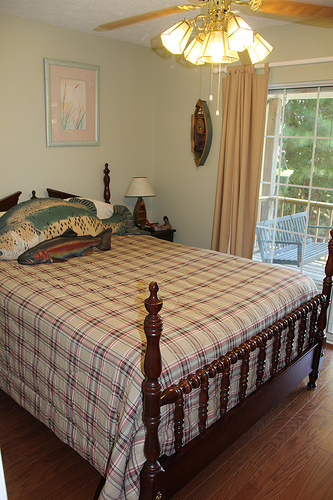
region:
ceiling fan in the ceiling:
[132, 10, 297, 81]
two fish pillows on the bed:
[6, 180, 145, 271]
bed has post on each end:
[137, 295, 187, 389]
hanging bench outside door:
[267, 152, 326, 272]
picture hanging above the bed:
[36, 51, 136, 156]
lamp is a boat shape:
[124, 195, 157, 240]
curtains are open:
[213, 71, 283, 300]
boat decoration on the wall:
[186, 90, 224, 183]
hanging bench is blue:
[269, 216, 331, 266]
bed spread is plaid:
[127, 241, 230, 299]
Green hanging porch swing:
[256, 214, 327, 258]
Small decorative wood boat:
[189, 94, 209, 166]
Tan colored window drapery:
[217, 68, 257, 254]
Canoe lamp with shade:
[124, 174, 152, 227]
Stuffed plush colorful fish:
[16, 228, 110, 265]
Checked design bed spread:
[5, 265, 133, 403]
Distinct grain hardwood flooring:
[254, 419, 330, 485]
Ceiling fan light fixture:
[162, 18, 268, 64]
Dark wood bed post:
[143, 279, 160, 492]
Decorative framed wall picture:
[43, 56, 100, 146]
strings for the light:
[199, 50, 231, 115]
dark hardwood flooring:
[227, 411, 296, 475]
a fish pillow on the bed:
[13, 217, 123, 268]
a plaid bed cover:
[3, 194, 299, 470]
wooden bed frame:
[114, 257, 331, 496]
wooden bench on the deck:
[238, 209, 331, 263]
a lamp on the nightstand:
[117, 166, 162, 235]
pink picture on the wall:
[37, 44, 115, 163]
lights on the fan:
[157, 22, 279, 74]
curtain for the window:
[213, 68, 290, 279]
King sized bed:
[0, 164, 331, 497]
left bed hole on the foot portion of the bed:
[139, 281, 165, 496]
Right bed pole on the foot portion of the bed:
[307, 228, 331, 386]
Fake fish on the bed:
[16, 228, 115, 264]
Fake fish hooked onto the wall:
[189, 97, 210, 168]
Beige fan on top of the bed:
[99, 0, 331, 116]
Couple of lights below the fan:
[153, 15, 272, 73]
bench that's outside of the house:
[252, 212, 329, 268]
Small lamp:
[123, 173, 154, 227]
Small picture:
[42, 59, 99, 147]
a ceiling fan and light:
[103, 4, 328, 65]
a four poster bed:
[8, 159, 327, 491]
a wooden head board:
[0, 165, 111, 240]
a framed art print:
[39, 57, 102, 150]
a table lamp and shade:
[121, 176, 157, 230]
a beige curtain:
[207, 63, 266, 260]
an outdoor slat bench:
[247, 205, 322, 268]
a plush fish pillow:
[13, 224, 111, 263]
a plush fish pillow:
[0, 192, 133, 266]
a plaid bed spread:
[3, 215, 324, 489]